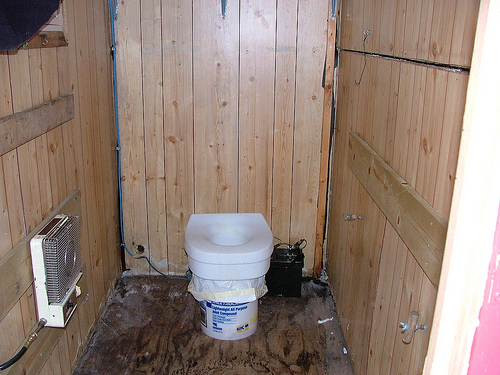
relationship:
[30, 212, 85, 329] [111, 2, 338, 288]
heater on wall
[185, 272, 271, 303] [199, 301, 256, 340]
bag in bucket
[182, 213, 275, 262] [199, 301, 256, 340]
seat on a bucket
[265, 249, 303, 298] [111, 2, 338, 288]
battery by wall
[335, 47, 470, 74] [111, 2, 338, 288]
pipe on wall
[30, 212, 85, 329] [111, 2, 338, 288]
heater on a wall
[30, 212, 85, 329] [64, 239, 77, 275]
heater has a fan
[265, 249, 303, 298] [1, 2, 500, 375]
battery in room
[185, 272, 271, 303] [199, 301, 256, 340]
bag in a bucket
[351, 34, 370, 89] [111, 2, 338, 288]
hook on a wall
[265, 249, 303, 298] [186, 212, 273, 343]
battery near a toilet